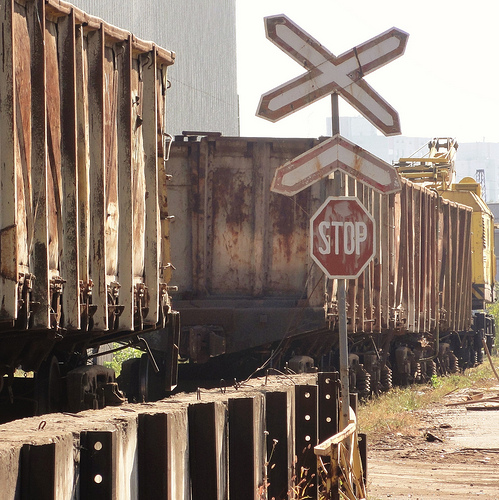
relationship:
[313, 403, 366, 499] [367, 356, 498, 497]
fence on side of road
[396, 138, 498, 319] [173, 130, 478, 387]
machine behind box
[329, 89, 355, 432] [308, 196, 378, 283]
pole underneath stop sign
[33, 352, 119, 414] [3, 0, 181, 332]
wheel under box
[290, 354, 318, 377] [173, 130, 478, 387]
wheel under box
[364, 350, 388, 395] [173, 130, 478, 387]
wheel under box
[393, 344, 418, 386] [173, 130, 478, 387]
wheel under box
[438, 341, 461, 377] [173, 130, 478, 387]
wheel under box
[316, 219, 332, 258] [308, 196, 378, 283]
letter on stop sign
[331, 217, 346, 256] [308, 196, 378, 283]
letter on stop sign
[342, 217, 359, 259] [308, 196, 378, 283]
letter on stop sign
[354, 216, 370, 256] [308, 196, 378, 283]
letter on stop sign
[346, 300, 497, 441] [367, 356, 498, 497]
grass next to road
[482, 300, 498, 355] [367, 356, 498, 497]
weeds are next to road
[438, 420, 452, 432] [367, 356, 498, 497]
rock on road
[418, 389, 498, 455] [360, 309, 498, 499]
asphalt on ground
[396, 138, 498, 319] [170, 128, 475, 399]
machine in front of train car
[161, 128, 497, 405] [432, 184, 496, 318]
train has head